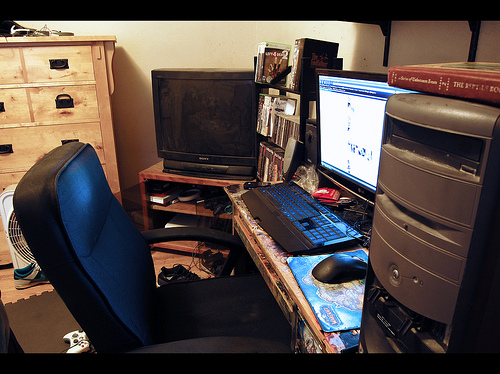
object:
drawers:
[22, 44, 94, 83]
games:
[149, 191, 177, 207]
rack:
[149, 202, 234, 220]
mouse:
[310, 254, 366, 284]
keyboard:
[238, 178, 366, 255]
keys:
[301, 221, 311, 228]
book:
[384, 62, 499, 103]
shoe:
[155, 264, 200, 287]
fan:
[0, 183, 38, 269]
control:
[60, 328, 88, 353]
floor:
[0, 250, 233, 365]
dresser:
[0, 34, 124, 268]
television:
[149, 65, 264, 182]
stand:
[135, 162, 257, 258]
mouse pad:
[283, 248, 375, 334]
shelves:
[257, 140, 288, 162]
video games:
[256, 94, 263, 135]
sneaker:
[10, 261, 51, 290]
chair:
[13, 142, 294, 353]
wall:
[340, 21, 500, 194]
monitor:
[318, 71, 416, 204]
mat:
[3, 289, 93, 353]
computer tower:
[357, 92, 500, 354]